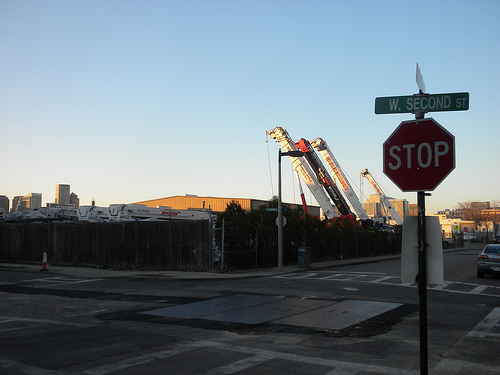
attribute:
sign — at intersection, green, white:
[373, 91, 471, 114]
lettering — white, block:
[388, 141, 451, 172]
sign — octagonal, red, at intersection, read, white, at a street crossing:
[381, 115, 459, 193]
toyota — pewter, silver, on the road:
[475, 240, 500, 280]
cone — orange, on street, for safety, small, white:
[39, 248, 52, 273]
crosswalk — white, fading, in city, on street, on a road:
[269, 266, 499, 301]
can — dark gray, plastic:
[295, 244, 317, 270]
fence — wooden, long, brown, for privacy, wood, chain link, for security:
[1, 217, 403, 272]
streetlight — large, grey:
[275, 147, 305, 271]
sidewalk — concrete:
[2, 254, 412, 283]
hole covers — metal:
[271, 294, 406, 333]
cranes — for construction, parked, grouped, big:
[267, 127, 341, 223]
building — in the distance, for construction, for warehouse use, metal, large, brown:
[134, 195, 322, 228]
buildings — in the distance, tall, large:
[52, 181, 72, 206]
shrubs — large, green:
[218, 201, 262, 271]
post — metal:
[414, 191, 431, 374]